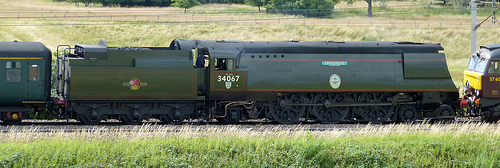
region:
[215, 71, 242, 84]
Train engine identification number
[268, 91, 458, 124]
Metal wheels on train engine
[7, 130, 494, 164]
Tall grass covered field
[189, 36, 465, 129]
Sleek black train engine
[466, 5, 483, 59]
Metal train signal pole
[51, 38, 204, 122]
Train engine tender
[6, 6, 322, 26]
Pasture boundary fence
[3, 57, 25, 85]
Window on train car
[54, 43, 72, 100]
Ladder on back of train car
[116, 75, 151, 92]
Company logo on train car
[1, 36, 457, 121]
Long dark train cars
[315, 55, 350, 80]
Design on side of train car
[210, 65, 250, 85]
The number 34067 on car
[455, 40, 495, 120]
A train engine with yellow on it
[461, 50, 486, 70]
Train windshield with wipers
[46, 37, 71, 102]
Ladder on end of car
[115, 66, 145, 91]
A red and yellow design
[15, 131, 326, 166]
Grass near railroad line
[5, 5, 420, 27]
Fence on other side of train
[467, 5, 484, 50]
A metal pole beside train track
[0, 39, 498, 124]
A train is traveling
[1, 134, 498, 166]
The grass is tall and green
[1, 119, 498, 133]
Some tall dead grass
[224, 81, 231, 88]
The shield is blue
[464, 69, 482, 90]
The paint is yellow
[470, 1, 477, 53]
A tall metal pole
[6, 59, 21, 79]
Train window is open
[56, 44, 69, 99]
Ladder on train car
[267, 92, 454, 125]
The wheels are black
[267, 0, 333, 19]
Bushes in the distance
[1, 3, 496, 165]
a freight train in the field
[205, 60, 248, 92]
the number on train 34067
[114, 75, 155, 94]
an emblem on side the train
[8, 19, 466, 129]
cars of freight train are black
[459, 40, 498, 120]
a yellow and gray car of train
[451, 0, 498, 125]
a gray pole near the railroad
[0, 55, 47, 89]
windows of train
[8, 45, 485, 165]
the train in passing a green grass field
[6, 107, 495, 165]
green grass is tall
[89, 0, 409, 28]
green trees on the field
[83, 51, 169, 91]
Tanker in the photo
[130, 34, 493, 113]
Train in the photo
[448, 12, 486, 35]
Poles in the photo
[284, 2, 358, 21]
Trees at the back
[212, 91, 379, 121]
Train wheels in the photo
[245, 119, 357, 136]
Track ballast in the photo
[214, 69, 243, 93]
Text on the train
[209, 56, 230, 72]
A person in the train.